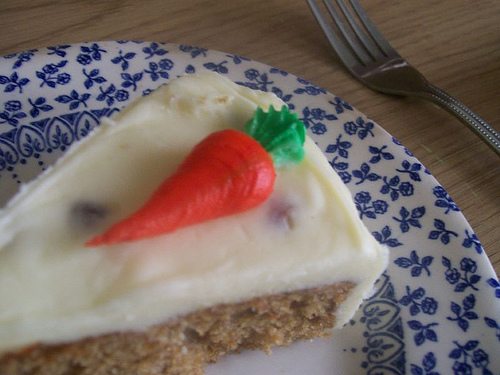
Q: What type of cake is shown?
A: Carrot.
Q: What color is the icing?
A: White.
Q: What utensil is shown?
A: Fork.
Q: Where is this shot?
A: Table.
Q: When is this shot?
A: Daytime.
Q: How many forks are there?
A: 1.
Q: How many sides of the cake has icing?
A: 2.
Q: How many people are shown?
A: 0.